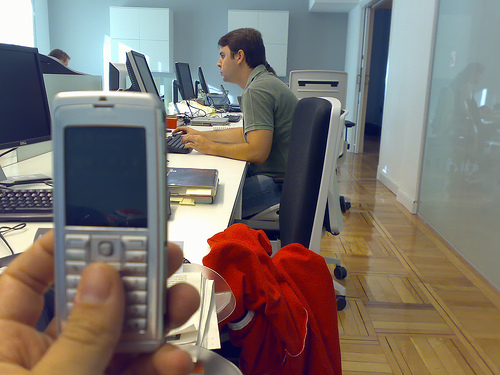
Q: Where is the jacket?
A: Hanging over the chair.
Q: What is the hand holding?
A: A cell phone.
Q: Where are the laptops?
A: On the long table.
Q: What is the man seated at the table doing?
A: Using a laptop.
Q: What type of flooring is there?
A: Wooden.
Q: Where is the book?
A: On the table.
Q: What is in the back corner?
A: A file cabinet.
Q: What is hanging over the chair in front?
A: A red jacket.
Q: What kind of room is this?
A: Office.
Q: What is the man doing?
A: On a computer.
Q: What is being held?
A: Phone.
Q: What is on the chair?
A: Jacket.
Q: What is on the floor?
A: Wood.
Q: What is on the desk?
A: Computers.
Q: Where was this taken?
A: Computer lab.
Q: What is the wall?
A: Glass.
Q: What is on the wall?
A: Window.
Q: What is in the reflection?
A: Books.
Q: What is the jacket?
A: Red.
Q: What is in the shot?
A: The phone.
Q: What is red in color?
A: The cloth.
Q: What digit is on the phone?
A: Thumb.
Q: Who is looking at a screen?
A: The man.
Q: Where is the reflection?
A: On the glass.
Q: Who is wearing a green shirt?
A: The man.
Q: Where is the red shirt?
A: On the chair.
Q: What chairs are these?
A: Office chairs.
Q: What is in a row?
A: Computers.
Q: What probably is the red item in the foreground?
A: Jacket.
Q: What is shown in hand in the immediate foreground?
A: Cell phone.